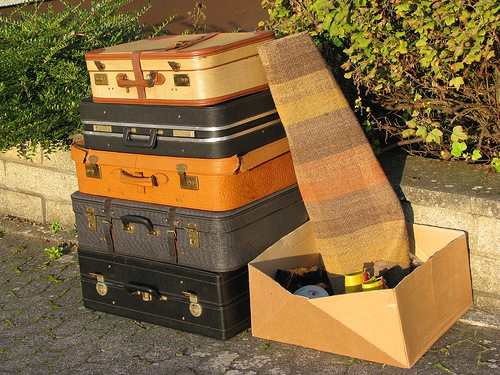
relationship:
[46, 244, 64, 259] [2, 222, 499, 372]
weed growing out of road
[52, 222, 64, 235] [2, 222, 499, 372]
weed growing out of road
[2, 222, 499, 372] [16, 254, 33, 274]
road has crack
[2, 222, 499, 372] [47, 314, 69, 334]
road has crack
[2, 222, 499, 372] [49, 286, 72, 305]
road has crack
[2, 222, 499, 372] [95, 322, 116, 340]
road has crack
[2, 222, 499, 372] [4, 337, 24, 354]
road has crack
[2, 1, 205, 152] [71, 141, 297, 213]
bush behind suitcase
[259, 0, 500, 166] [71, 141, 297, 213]
bush behind suitcase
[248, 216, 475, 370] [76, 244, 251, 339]
box next to suitcase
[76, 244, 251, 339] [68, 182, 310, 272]
suitcase underneath suitcase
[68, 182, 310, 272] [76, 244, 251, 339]
suitcase on top of suitcase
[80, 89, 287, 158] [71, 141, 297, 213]
suitcase on top of suitcase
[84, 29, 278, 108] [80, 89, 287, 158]
suitcase on top of suitcase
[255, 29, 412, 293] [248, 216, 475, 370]
blanket inside of box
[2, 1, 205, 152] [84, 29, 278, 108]
bush next to suitcase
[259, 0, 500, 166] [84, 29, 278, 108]
bush next to suitcase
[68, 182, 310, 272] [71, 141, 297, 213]
suitcase underneath suitcase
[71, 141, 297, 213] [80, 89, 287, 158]
suitcase underneath suitcase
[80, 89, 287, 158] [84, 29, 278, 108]
suitcase underneath suitcase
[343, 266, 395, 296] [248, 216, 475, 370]
object inside of box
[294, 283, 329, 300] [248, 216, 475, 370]
object inside of box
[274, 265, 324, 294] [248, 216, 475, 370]
object inside of box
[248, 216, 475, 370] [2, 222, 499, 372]
box on top of road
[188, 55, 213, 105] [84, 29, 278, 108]
light reflected on top of suitcase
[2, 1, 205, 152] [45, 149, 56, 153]
bush has leaf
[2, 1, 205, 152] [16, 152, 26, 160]
bush has leaf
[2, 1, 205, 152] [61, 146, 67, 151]
bush has leaf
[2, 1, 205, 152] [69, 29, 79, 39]
bush has leaf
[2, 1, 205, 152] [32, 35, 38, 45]
bush has leaf